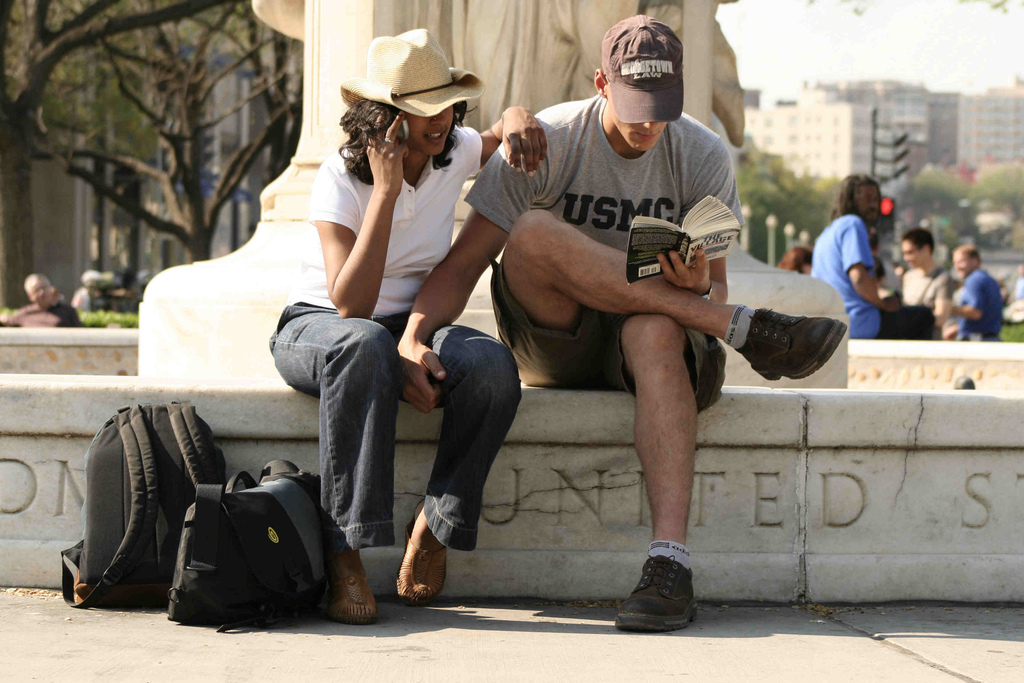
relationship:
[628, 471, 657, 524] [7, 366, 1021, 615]
letter on wall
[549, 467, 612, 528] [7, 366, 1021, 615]
letter on wall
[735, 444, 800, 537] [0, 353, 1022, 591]
letter on wall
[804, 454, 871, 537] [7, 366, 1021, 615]
letter on wall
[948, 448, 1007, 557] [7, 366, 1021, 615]
letter on wall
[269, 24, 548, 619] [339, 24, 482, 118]
woman wearing cowboy hat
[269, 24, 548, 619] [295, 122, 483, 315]
woman wearing shirt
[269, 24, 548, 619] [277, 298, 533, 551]
woman wearing jeans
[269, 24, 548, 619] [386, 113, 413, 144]
woman talking on cell phone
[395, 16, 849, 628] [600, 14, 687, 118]
man wearing baseball cap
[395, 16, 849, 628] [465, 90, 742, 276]
man wearing shirt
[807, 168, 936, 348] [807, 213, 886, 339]
man wearing shirt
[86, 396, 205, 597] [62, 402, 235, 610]
straps on backpack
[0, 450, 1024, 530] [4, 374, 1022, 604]
words carved in stone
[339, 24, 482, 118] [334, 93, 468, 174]
cowboy hat on head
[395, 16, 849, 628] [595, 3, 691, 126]
man wearing baseball cap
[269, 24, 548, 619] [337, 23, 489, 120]
woman wearing cowboy hat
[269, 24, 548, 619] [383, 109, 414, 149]
woman holding cell phone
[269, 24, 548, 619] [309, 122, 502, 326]
woman wears shirt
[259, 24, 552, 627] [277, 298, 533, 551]
woman wears jeans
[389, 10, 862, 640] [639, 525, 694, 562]
man wears sock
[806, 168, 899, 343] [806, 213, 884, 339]
man wears shirt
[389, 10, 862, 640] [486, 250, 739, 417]
man wears shorts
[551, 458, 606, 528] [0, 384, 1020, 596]
letter in wall